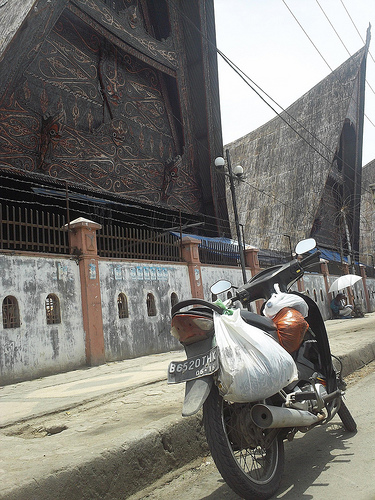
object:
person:
[329, 292, 353, 318]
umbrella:
[327, 273, 362, 292]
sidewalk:
[0, 311, 373, 491]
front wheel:
[325, 389, 358, 436]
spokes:
[226, 406, 277, 486]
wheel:
[200, 373, 285, 497]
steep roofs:
[0, 0, 370, 263]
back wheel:
[203, 384, 287, 500]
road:
[136, 356, 371, 498]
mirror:
[294, 237, 318, 254]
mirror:
[209, 279, 233, 294]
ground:
[321, 316, 372, 331]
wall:
[300, 274, 351, 315]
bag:
[212, 298, 297, 403]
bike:
[165, 234, 354, 500]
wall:
[0, 253, 87, 383]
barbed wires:
[0, 175, 373, 264]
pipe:
[250, 403, 318, 430]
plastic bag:
[263, 283, 309, 320]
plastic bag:
[273, 309, 308, 350]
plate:
[167, 346, 220, 385]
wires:
[215, 2, 375, 149]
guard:
[180, 371, 213, 419]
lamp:
[233, 164, 244, 180]